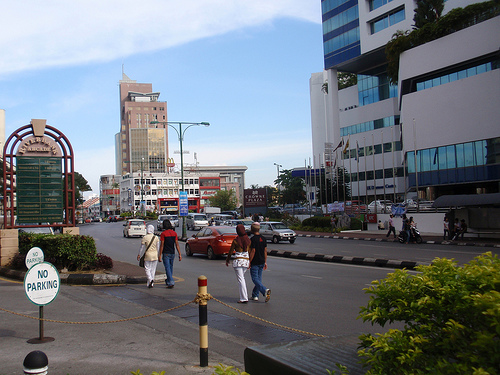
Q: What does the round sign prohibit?
A: Parking.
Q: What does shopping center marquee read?
A: Riverbank.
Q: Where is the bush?
A: Planter on right.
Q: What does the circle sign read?
A: No parking.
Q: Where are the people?
A: Crossing street.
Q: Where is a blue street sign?
A: Pole in street center.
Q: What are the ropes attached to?
A: Black and yellow post.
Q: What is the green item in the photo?
A: Bush.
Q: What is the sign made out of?
A: Stone.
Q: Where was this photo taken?
A: In a city.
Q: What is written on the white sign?
A: No Parking.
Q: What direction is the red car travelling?
A: Away from the camera.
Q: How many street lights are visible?
A: Two.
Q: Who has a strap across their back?
A: The woman in the yellow shirt and white pants.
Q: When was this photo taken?
A: During the day.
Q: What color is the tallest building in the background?
A: Brown.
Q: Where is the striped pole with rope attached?
A: In the front, center of the photo.